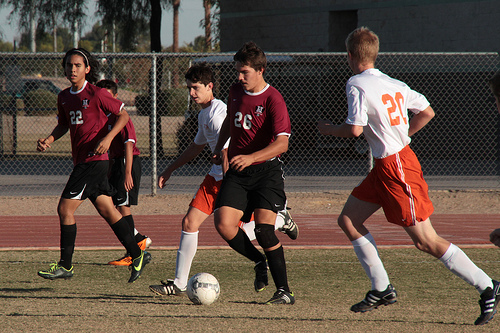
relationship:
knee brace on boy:
[250, 217, 281, 251] [212, 43, 295, 307]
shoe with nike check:
[123, 254, 152, 281] [130, 252, 143, 272]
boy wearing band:
[36, 46, 153, 283] [69, 46, 90, 66]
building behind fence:
[217, 0, 498, 159] [218, 33, 497, 209]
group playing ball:
[45, 25, 495, 320] [192, 271, 219, 303]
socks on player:
[336, 231, 476, 288] [298, 16, 480, 287]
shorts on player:
[349, 144, 433, 224] [316, 25, 498, 326]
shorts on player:
[212, 156, 309, 216] [207, 47, 327, 310]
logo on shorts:
[273, 200, 282, 207] [212, 155, 291, 224]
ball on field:
[185, 272, 222, 306] [0, 250, 500, 330]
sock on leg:
[165, 227, 200, 290] [171, 195, 213, 287]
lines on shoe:
[363, 292, 382, 308] [304, 262, 419, 320]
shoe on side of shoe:
[128, 251, 152, 283] [126, 250, 152, 283]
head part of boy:
[58, 46, 101, 87] [32, 45, 153, 285]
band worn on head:
[72, 47, 90, 67] [58, 46, 101, 87]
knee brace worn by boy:
[252, 223, 279, 249] [211, 40, 303, 310]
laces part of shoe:
[42, 257, 58, 277] [35, 263, 74, 280]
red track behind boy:
[4, 216, 60, 244] [36, 46, 153, 283]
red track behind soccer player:
[4, 216, 60, 244] [147, 65, 298, 296]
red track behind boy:
[4, 216, 60, 244] [212, 43, 295, 307]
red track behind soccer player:
[4, 216, 60, 244] [334, 26, 498, 325]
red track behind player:
[4, 216, 60, 244] [94, 79, 152, 266]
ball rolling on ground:
[185, 271, 222, 308] [0, 75, 496, 329]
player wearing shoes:
[105, 83, 150, 265] [136, 240, 145, 248]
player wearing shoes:
[105, 83, 150, 265] [116, 256, 125, 265]